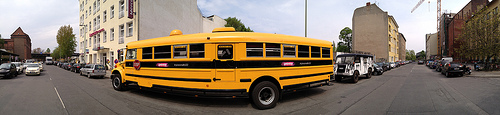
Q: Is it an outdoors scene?
A: Yes, it is outdoors.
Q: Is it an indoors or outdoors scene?
A: It is outdoors.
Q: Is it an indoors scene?
A: No, it is outdoors.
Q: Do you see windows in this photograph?
A: Yes, there is a window.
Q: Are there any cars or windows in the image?
A: Yes, there is a window.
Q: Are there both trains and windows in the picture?
A: No, there is a window but no trains.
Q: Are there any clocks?
A: No, there are no clocks.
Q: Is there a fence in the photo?
A: No, there are no fences.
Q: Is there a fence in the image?
A: No, there are no fences.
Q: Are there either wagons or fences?
A: No, there are no fences or wagons.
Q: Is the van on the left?
A: Yes, the van is on the left of the image.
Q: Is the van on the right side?
A: No, the van is on the left of the image.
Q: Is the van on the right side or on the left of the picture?
A: The van is on the left of the image.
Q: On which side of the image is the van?
A: The van is on the left of the image.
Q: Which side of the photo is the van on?
A: The van is on the left of the image.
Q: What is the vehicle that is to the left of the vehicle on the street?
A: The vehicle is a van.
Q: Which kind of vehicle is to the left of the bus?
A: The vehicle is a van.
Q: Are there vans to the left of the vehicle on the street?
A: Yes, there is a van to the left of the bus.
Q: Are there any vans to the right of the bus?
A: No, the van is to the left of the bus.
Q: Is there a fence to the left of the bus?
A: No, there is a van to the left of the bus.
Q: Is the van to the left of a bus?
A: Yes, the van is to the left of a bus.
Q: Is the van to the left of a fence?
A: No, the van is to the left of a bus.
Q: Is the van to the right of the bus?
A: No, the van is to the left of the bus.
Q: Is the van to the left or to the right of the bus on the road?
A: The van is to the left of the bus.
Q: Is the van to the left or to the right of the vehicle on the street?
A: The van is to the left of the bus.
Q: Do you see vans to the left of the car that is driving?
A: No, the van is to the right of the car.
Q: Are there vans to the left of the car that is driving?
A: No, the van is to the right of the car.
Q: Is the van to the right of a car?
A: Yes, the van is to the right of a car.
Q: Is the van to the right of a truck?
A: No, the van is to the right of a car.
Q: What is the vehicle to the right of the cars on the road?
A: The vehicle is a van.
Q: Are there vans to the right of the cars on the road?
A: Yes, there is a van to the right of the cars.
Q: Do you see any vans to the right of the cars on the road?
A: Yes, there is a van to the right of the cars.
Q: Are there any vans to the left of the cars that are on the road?
A: No, the van is to the right of the cars.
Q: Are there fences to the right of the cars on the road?
A: No, there is a van to the right of the cars.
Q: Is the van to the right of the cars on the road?
A: Yes, the van is to the right of the cars.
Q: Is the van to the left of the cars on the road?
A: No, the van is to the right of the cars.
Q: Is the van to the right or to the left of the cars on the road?
A: The van is to the right of the cars.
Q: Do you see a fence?
A: No, there are no fences.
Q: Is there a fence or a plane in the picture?
A: No, there are no fences or airplanes.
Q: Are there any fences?
A: No, there are no fences.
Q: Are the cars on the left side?
A: Yes, the cars are on the left of the image.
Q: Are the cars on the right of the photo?
A: No, the cars are on the left of the image.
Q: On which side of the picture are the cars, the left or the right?
A: The cars are on the left of the image.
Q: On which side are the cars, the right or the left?
A: The cars are on the left of the image.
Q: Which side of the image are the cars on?
A: The cars are on the left of the image.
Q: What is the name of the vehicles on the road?
A: The vehicles are cars.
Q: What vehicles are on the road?
A: The vehicles are cars.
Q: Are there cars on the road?
A: Yes, there are cars on the road.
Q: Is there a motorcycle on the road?
A: No, there are cars on the road.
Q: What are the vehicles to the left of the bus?
A: The vehicles are cars.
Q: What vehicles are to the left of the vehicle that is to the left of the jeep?
A: The vehicles are cars.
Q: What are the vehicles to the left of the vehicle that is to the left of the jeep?
A: The vehicles are cars.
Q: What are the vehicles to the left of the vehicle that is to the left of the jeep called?
A: The vehicles are cars.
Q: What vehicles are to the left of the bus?
A: The vehicles are cars.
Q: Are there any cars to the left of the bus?
A: Yes, there are cars to the left of the bus.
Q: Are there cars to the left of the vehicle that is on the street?
A: Yes, there are cars to the left of the bus.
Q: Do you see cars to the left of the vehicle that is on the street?
A: Yes, there are cars to the left of the bus.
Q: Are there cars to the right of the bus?
A: No, the cars are to the left of the bus.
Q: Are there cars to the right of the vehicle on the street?
A: No, the cars are to the left of the bus.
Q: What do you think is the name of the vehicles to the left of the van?
A: The vehicles are cars.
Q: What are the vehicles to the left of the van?
A: The vehicles are cars.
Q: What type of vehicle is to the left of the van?
A: The vehicles are cars.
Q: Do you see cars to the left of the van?
A: Yes, there are cars to the left of the van.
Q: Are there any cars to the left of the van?
A: Yes, there are cars to the left of the van.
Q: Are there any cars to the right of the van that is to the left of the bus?
A: No, the cars are to the left of the van.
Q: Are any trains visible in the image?
A: No, there are no trains.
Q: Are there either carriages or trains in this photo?
A: No, there are no trains or carriages.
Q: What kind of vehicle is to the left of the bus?
A: The vehicle is a car.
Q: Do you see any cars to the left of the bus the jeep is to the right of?
A: Yes, there is a car to the left of the bus.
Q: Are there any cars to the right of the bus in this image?
A: No, the car is to the left of the bus.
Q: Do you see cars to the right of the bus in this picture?
A: No, the car is to the left of the bus.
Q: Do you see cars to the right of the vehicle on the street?
A: No, the car is to the left of the bus.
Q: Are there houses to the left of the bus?
A: No, there is a car to the left of the bus.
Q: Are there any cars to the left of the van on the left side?
A: Yes, there is a car to the left of the van.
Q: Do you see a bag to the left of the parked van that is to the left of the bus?
A: No, there is a car to the left of the van.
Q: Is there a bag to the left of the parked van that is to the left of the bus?
A: No, there is a car to the left of the van.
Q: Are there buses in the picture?
A: Yes, there is a bus.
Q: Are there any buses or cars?
A: Yes, there is a bus.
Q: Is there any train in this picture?
A: No, there are no trains.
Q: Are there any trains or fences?
A: No, there are no trains or fences.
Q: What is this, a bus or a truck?
A: This is a bus.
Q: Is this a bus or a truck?
A: This is a bus.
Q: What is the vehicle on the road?
A: The vehicle is a bus.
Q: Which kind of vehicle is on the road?
A: The vehicle is a bus.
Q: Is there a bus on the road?
A: Yes, there is a bus on the road.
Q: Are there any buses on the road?
A: Yes, there is a bus on the road.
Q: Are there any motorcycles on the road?
A: No, there is a bus on the road.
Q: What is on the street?
A: The bus is on the street.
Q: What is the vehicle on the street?
A: The vehicle is a bus.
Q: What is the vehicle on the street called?
A: The vehicle is a bus.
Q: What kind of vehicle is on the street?
A: The vehicle is a bus.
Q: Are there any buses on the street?
A: Yes, there is a bus on the street.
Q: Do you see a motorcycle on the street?
A: No, there is a bus on the street.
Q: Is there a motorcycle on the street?
A: No, there is a bus on the street.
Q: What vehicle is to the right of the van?
A: The vehicle is a bus.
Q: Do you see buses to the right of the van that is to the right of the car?
A: Yes, there is a bus to the right of the van.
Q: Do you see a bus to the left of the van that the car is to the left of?
A: No, the bus is to the right of the van.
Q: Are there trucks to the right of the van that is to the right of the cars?
A: No, there is a bus to the right of the van.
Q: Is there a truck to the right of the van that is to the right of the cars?
A: No, there is a bus to the right of the van.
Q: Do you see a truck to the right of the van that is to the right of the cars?
A: No, there is a bus to the right of the van.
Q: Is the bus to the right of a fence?
A: No, the bus is to the right of the van.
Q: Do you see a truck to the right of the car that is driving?
A: No, there is a bus to the right of the car.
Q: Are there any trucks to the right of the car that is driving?
A: No, there is a bus to the right of the car.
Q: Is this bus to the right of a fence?
A: No, the bus is to the right of a car.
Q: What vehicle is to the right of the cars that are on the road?
A: The vehicle is a bus.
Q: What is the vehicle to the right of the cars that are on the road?
A: The vehicle is a bus.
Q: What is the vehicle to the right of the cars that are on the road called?
A: The vehicle is a bus.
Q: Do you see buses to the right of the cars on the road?
A: Yes, there is a bus to the right of the cars.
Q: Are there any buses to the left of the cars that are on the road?
A: No, the bus is to the right of the cars.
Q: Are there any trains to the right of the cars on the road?
A: No, there is a bus to the right of the cars.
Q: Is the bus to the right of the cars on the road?
A: Yes, the bus is to the right of the cars.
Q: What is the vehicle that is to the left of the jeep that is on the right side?
A: The vehicle is a bus.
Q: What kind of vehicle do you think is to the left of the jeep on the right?
A: The vehicle is a bus.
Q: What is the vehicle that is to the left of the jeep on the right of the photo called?
A: The vehicle is a bus.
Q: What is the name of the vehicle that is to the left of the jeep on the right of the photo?
A: The vehicle is a bus.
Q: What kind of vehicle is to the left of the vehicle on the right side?
A: The vehicle is a bus.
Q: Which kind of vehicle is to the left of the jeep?
A: The vehicle is a bus.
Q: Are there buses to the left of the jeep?
A: Yes, there is a bus to the left of the jeep.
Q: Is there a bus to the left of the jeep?
A: Yes, there is a bus to the left of the jeep.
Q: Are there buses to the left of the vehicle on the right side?
A: Yes, there is a bus to the left of the jeep.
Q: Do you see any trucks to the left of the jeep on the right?
A: No, there is a bus to the left of the jeep.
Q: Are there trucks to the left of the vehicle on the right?
A: No, there is a bus to the left of the jeep.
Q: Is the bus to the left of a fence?
A: No, the bus is to the left of the jeep.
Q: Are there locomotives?
A: No, there are no locomotives.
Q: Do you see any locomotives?
A: No, there are no locomotives.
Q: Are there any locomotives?
A: No, there are no locomotives.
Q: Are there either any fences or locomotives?
A: No, there are no locomotives or fences.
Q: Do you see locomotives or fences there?
A: No, there are no locomotives or fences.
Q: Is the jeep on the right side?
A: Yes, the jeep is on the right of the image.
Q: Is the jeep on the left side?
A: No, the jeep is on the right of the image.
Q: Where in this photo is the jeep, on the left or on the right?
A: The jeep is on the right of the image.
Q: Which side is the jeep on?
A: The jeep is on the right of the image.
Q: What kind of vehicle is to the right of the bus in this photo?
A: The vehicle is a jeep.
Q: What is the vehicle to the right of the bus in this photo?
A: The vehicle is a jeep.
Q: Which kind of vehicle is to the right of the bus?
A: The vehicle is a jeep.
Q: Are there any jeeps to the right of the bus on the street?
A: Yes, there is a jeep to the right of the bus.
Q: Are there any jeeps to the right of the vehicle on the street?
A: Yes, there is a jeep to the right of the bus.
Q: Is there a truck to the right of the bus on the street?
A: No, there is a jeep to the right of the bus.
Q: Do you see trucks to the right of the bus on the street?
A: No, there is a jeep to the right of the bus.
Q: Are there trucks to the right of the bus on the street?
A: No, there is a jeep to the right of the bus.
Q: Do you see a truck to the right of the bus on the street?
A: No, there is a jeep to the right of the bus.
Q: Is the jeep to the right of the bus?
A: Yes, the jeep is to the right of the bus.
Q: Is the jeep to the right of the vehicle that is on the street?
A: Yes, the jeep is to the right of the bus.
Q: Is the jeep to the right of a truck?
A: No, the jeep is to the right of the bus.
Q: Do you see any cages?
A: No, there are no cages.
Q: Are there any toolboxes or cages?
A: No, there are no cages or toolboxes.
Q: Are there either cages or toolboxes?
A: No, there are no cages or toolboxes.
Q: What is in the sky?
A: The clouds are in the sky.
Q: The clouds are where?
A: The clouds are in the sky.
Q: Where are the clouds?
A: The clouds are in the sky.